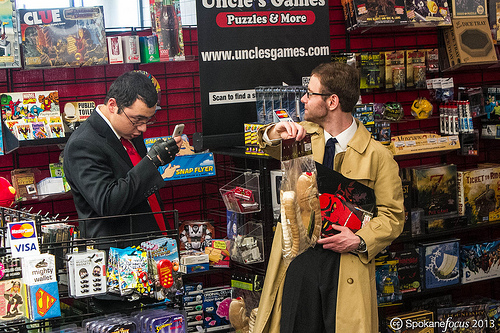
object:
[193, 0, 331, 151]
banner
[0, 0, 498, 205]
wall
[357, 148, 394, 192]
floor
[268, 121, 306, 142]
hand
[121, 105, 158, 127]
glasses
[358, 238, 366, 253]
watch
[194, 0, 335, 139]
sign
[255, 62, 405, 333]
man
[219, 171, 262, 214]
bin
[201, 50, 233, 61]
letters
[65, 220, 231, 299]
multiple items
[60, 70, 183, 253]
man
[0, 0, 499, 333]
store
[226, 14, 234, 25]
letter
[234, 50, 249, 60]
letter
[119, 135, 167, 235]
tie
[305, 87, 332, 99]
glasses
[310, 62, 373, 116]
hair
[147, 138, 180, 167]
fingerless glove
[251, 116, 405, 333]
coat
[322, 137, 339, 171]
tie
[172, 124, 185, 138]
cell phone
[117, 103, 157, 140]
face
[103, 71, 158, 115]
hair